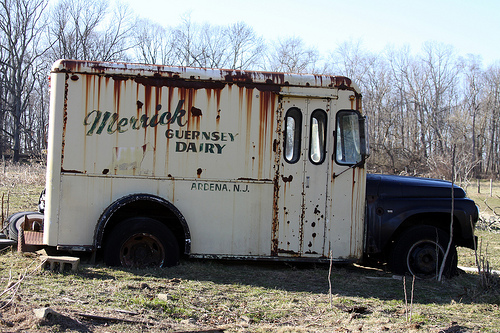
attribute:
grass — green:
[2, 159, 499, 332]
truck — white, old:
[41, 58, 476, 280]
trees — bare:
[0, 0, 498, 181]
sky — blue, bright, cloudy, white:
[3, 2, 499, 109]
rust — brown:
[62, 60, 281, 158]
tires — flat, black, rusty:
[105, 217, 456, 279]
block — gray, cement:
[42, 256, 77, 272]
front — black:
[366, 175, 479, 262]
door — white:
[276, 94, 328, 256]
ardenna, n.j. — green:
[189, 181, 251, 191]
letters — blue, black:
[83, 98, 248, 192]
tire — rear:
[100, 212, 181, 267]